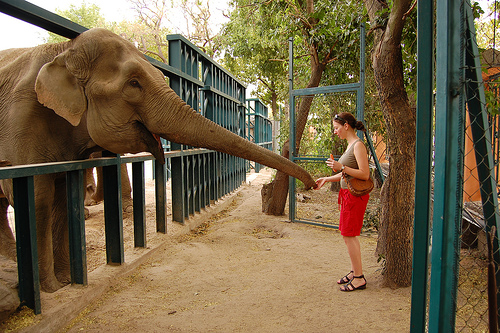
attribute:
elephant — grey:
[15, 37, 321, 288]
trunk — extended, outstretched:
[129, 89, 313, 188]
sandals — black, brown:
[333, 265, 373, 302]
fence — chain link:
[461, 15, 500, 328]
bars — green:
[172, 49, 247, 192]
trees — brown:
[253, 1, 422, 292]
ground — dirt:
[158, 223, 334, 331]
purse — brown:
[347, 146, 368, 203]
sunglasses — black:
[330, 105, 351, 133]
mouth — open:
[124, 122, 207, 165]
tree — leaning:
[268, 22, 330, 208]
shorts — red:
[333, 183, 365, 236]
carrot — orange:
[323, 151, 336, 173]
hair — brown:
[328, 110, 372, 135]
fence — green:
[163, 57, 243, 194]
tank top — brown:
[340, 141, 373, 203]